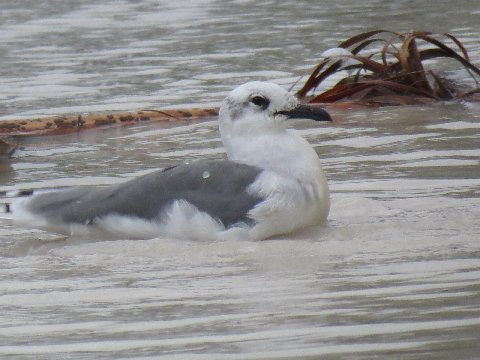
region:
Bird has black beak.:
[286, 102, 359, 155]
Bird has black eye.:
[238, 77, 277, 132]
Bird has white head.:
[241, 79, 291, 103]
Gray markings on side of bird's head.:
[225, 97, 244, 118]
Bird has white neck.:
[225, 131, 292, 150]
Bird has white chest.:
[286, 171, 338, 219]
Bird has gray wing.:
[107, 181, 229, 204]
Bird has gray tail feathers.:
[24, 191, 98, 227]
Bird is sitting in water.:
[108, 168, 345, 270]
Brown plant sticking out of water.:
[339, 32, 428, 114]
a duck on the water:
[21, 19, 442, 304]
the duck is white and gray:
[22, 63, 358, 267]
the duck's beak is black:
[208, 67, 336, 146]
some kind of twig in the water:
[300, 11, 473, 120]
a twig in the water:
[25, 72, 228, 141]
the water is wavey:
[2, 251, 436, 337]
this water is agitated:
[31, 27, 440, 257]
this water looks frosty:
[15, 21, 460, 290]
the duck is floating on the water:
[23, 67, 354, 251]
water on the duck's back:
[104, 136, 253, 218]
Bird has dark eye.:
[236, 95, 266, 112]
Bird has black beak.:
[289, 94, 346, 131]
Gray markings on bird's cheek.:
[223, 94, 247, 139]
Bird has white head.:
[241, 76, 273, 97]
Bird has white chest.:
[275, 129, 327, 185]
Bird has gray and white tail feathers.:
[12, 191, 105, 220]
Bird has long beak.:
[291, 101, 357, 144]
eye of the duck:
[236, 85, 303, 124]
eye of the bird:
[239, 75, 277, 120]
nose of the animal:
[282, 81, 336, 133]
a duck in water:
[13, 56, 469, 341]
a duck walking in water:
[31, 90, 447, 331]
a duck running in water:
[44, 83, 454, 337]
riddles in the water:
[256, 273, 468, 353]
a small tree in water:
[306, 10, 454, 98]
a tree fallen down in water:
[37, 36, 473, 134]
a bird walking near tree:
[28, 66, 371, 303]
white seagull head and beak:
[12, 81, 348, 248]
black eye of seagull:
[248, 91, 269, 106]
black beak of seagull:
[288, 99, 332, 127]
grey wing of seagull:
[63, 164, 258, 223]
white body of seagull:
[248, 148, 332, 219]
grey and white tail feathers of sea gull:
[4, 181, 74, 240]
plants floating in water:
[326, 27, 454, 107]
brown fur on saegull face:
[227, 96, 252, 131]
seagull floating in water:
[0, 66, 332, 292]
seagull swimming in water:
[0, 75, 369, 291]